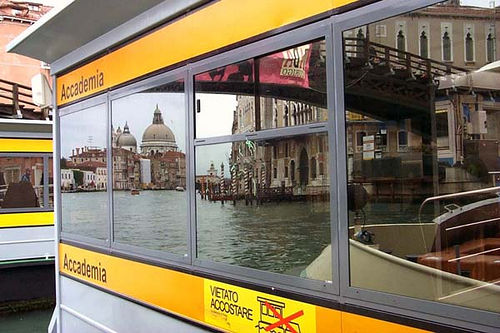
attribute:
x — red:
[264, 299, 307, 333]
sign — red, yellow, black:
[203, 278, 317, 332]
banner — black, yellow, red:
[178, 41, 310, 87]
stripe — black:
[55, 0, 212, 79]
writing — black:
[59, 69, 107, 102]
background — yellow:
[57, 0, 354, 108]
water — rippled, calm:
[62, 192, 499, 279]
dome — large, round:
[141, 103, 178, 145]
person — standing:
[35, 59, 57, 122]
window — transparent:
[57, 0, 499, 331]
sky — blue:
[62, 92, 237, 178]